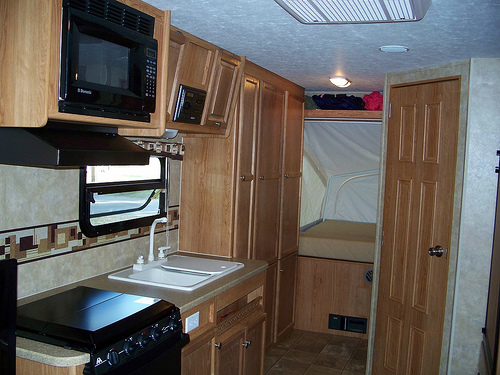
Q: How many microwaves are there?
A: One.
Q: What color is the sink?
A: White.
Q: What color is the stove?
A: Black.